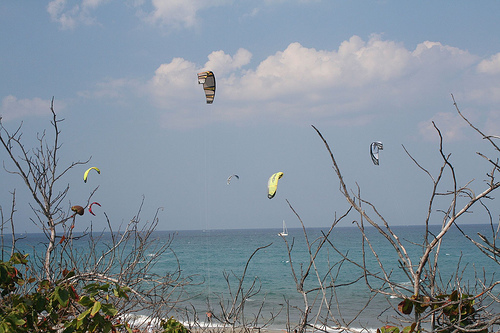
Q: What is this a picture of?
A: The ocean.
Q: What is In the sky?
A: Clouds.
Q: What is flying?
A: Kites.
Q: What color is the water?
A: Blue.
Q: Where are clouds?
A: In the sky.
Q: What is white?
A: Clouds.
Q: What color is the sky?
A: Blue.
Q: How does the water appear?
A: Calm.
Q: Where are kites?
A: In the air.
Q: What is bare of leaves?
A: Branches.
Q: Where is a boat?
A: In the water.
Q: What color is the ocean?
A: Blue.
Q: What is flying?
A: Kites.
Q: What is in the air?
A: Kites.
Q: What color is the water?
A: Blue and white.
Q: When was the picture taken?
A: Daytime.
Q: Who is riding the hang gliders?
A: People.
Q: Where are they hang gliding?
A: Over the ocean.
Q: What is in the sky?
A: Hang gliders.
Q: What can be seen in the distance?
A: A sailboat.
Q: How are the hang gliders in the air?
A: Wind.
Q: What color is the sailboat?
A: White.